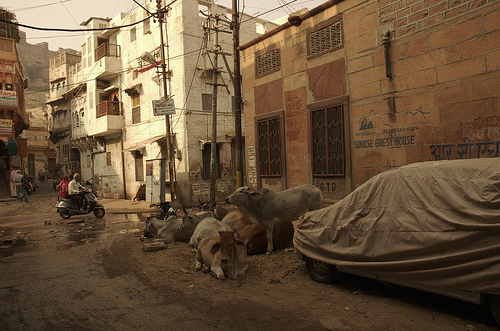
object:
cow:
[225, 184, 324, 256]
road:
[0, 178, 499, 331]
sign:
[151, 99, 176, 117]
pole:
[232, 0, 245, 189]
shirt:
[56, 175, 70, 198]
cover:
[293, 157, 499, 294]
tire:
[305, 257, 336, 283]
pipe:
[382, 31, 391, 77]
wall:
[241, 0, 500, 211]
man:
[68, 172, 86, 212]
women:
[56, 175, 70, 199]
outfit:
[56, 175, 70, 198]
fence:
[311, 105, 346, 176]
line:
[204, 0, 327, 43]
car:
[292, 157, 500, 323]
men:
[12, 170, 23, 202]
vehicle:
[292, 157, 500, 330]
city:
[0, 0, 499, 331]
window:
[306, 13, 342, 61]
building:
[236, 0, 500, 208]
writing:
[354, 107, 430, 149]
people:
[20, 173, 33, 203]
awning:
[237, 0, 333, 32]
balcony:
[67, 42, 121, 92]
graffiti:
[428, 137, 500, 161]